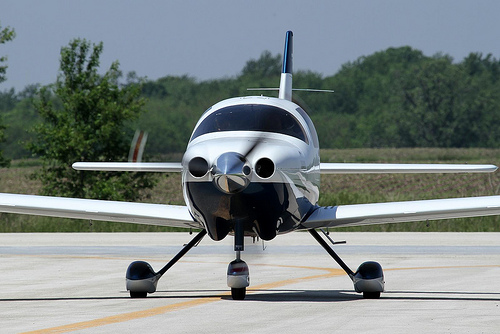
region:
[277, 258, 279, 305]
a group of wheels for landing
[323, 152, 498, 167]
a wing in the middle of plane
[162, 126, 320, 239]
front end of plane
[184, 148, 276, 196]
headlights on airplane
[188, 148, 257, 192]
silver nose of an airplane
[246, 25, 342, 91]
a tail of an airplane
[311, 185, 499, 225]
front wing of an airplane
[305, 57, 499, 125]
green trees in background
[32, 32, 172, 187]
a red and white object next to tree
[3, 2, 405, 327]
an small plane on runway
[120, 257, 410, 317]
The landing gear is down.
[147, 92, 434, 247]
A plane on the runway.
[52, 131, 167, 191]
The right wing of the plane.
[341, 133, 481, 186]
The left wing of the plane.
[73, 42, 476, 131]
Trees in the background.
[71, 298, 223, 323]
A yellow line in the runway.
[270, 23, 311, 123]
The tail of the plane is blue.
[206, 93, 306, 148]
The windshield of the plane.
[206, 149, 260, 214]
The nose of the plane.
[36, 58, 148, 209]
A tree sits on the side of the runway.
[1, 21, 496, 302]
plane on a runway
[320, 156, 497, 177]
long and thin airplane wing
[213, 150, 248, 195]
shiny nose of the plane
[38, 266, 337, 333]
faded yellow line painted on the runway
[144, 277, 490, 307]
shadow from the plane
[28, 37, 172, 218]
small green tree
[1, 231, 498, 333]
concrete runway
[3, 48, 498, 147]
thick greent rees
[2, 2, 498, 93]
clear blue sky with no clouds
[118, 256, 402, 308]
three little wheels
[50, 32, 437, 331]
small plane on runway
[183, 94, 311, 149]
windshield of plane is tinted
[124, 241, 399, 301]
three wheels on plane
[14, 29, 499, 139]
dense treeline in background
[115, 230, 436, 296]
yellow markings on runway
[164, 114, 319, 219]
propeller on front of plane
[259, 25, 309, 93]
blue tipped tail of plane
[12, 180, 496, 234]
wings on either side of plane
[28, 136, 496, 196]
large open field behind runway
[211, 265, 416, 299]
shadow of plane on runway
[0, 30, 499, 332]
small white airplane is on the runway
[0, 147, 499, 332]
white concrete runway is next to an agricultural field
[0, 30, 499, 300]
white airplane has three white and dark blue wheel covers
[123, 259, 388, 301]
dark blue and white wheel covers over black rubber wheels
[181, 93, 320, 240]
propellor is spinning in front of the black and white nose section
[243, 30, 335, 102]
tail is blue and white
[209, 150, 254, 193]
propelloer hub is silver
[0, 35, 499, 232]
tall green tree is in the front of the field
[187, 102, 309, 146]
tinted black cockpit windshield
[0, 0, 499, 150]
grey blue sky above green background trees